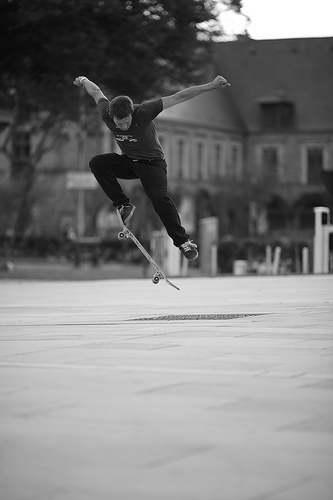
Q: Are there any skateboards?
A: Yes, there is a skateboard.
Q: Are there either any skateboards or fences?
A: Yes, there is a skateboard.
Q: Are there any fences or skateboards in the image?
A: Yes, there is a skateboard.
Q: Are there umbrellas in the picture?
A: No, there are no umbrellas.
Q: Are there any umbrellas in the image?
A: No, there are no umbrellas.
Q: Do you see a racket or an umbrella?
A: No, there are no umbrellas or rackets.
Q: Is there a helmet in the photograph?
A: No, there are no helmets.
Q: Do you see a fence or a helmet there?
A: No, there are no helmets or fences.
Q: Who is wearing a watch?
A: The boy is wearing a watch.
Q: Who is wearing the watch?
A: The boy is wearing a watch.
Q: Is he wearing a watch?
A: Yes, the boy is wearing a watch.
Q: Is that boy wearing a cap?
A: No, the boy is wearing a watch.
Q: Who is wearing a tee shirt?
A: The boy is wearing a tee shirt.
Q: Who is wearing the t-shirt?
A: The boy is wearing a tee shirt.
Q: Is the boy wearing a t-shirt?
A: Yes, the boy is wearing a t-shirt.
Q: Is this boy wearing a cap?
A: No, the boy is wearing a t-shirt.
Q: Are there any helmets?
A: No, there are no helmets.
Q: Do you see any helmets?
A: No, there are no helmets.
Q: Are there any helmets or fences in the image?
A: No, there are no helmets or fences.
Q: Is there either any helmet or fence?
A: No, there are no helmets or fences.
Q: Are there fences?
A: No, there are no fences.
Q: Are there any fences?
A: No, there are no fences.